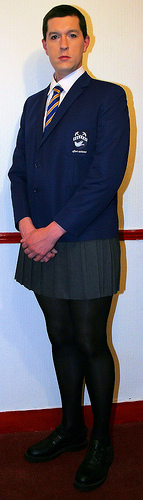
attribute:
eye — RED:
[68, 33, 76, 38]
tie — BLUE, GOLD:
[43, 84, 63, 135]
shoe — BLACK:
[73, 436, 113, 493]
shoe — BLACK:
[22, 421, 91, 463]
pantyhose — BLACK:
[40, 292, 122, 414]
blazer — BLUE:
[14, 68, 142, 204]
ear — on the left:
[83, 36, 88, 51]